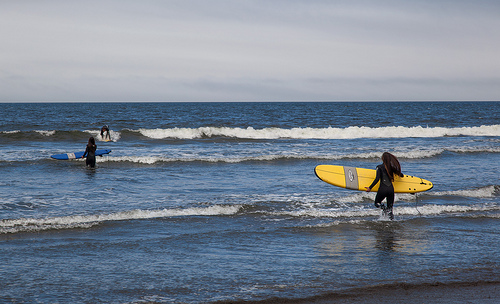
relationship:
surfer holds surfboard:
[367, 153, 400, 220] [314, 163, 434, 196]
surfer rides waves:
[96, 122, 114, 145] [140, 119, 496, 145]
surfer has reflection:
[367, 153, 400, 220] [370, 230, 397, 258]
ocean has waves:
[2, 105, 499, 276] [140, 119, 496, 145]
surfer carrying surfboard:
[367, 153, 400, 220] [314, 163, 434, 196]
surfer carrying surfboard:
[82, 139, 98, 167] [51, 148, 113, 161]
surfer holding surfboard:
[367, 153, 400, 220] [314, 163, 434, 196]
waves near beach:
[140, 119, 496, 145] [313, 278, 495, 301]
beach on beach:
[252, 266, 499, 304] [313, 278, 495, 301]